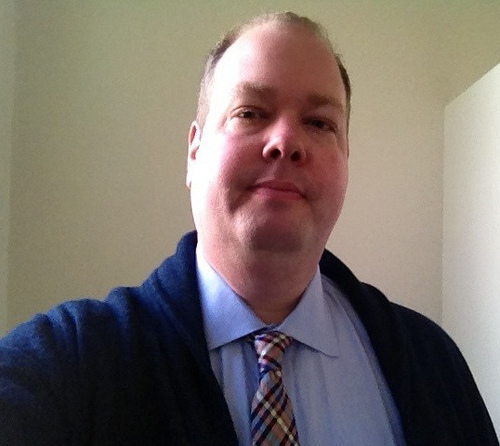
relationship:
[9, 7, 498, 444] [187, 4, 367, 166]
person has hair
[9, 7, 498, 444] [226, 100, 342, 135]
person has eyes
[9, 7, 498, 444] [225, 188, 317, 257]
person has chin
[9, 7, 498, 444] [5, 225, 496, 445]
person wearing sweater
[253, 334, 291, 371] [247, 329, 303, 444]
knot on tie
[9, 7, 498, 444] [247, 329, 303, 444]
person has tie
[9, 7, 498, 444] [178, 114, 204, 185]
person has ear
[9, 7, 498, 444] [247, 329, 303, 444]
person wearing tie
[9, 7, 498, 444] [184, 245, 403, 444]
person wearing shirt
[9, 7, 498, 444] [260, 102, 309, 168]
person has nose